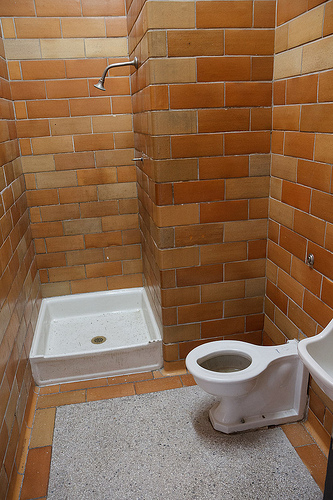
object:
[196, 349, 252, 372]
hole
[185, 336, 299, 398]
toilet seat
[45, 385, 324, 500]
floor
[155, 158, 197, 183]
brick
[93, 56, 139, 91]
wall mount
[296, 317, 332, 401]
sink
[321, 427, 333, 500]
pole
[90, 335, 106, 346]
drain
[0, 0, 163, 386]
shower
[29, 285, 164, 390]
bottom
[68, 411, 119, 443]
tile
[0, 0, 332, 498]
bathroom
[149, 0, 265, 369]
wall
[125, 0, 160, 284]
wall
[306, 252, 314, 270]
button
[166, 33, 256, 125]
tiles